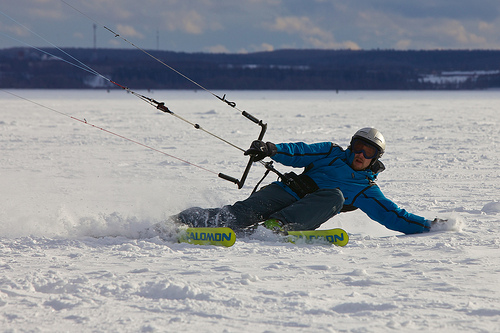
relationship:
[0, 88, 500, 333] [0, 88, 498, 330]
snow on hillside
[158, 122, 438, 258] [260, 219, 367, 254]
guy on ski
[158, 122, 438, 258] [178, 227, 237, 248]
guy on board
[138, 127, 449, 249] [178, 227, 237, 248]
guy on board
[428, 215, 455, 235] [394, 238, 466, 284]
left hand touching surface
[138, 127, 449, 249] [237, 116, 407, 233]
guy wearing coat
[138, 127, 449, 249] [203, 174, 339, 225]
guy wearing pants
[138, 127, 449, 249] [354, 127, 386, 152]
guy wearing helmet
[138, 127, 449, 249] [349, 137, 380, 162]
guy wearing goggles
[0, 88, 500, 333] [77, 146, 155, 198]
snow on hill side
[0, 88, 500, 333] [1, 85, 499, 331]
snow on hill side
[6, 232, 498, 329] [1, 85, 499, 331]
snow on hill side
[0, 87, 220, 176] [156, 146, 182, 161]
rope has part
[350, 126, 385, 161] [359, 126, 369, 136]
helmet has part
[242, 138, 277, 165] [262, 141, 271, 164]
glove has part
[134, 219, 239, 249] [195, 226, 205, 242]
board has edge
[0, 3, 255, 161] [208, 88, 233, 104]
rope has edge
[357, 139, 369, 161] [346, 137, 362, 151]
shadow has edge